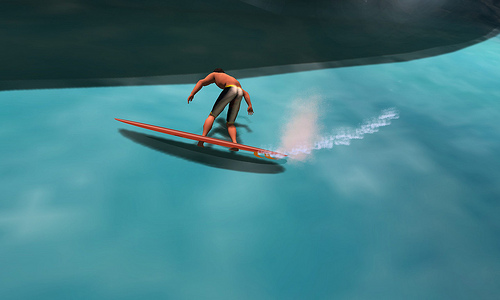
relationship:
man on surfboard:
[188, 61, 263, 141] [114, 116, 284, 173]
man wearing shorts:
[188, 61, 263, 141] [203, 87, 242, 120]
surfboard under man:
[114, 116, 284, 173] [188, 61, 263, 141]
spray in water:
[287, 110, 402, 162] [0, 162, 500, 298]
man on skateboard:
[188, 61, 263, 141] [114, 116, 284, 173]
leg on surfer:
[202, 110, 218, 140] [188, 61, 263, 141]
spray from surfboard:
[287, 110, 402, 162] [114, 116, 284, 173]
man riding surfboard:
[188, 61, 263, 141] [114, 116, 284, 173]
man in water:
[188, 61, 263, 141] [0, 162, 500, 298]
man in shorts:
[188, 61, 263, 141] [203, 87, 242, 120]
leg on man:
[225, 124, 244, 145] [188, 61, 263, 141]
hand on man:
[248, 104, 256, 116] [188, 61, 263, 141]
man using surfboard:
[188, 61, 263, 141] [114, 116, 284, 173]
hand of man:
[248, 104, 256, 116] [188, 61, 263, 141]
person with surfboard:
[188, 61, 263, 141] [114, 116, 284, 173]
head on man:
[213, 66, 225, 74] [188, 61, 263, 141]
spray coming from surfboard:
[287, 110, 402, 162] [114, 116, 284, 173]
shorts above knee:
[203, 87, 242, 120] [207, 114, 216, 124]